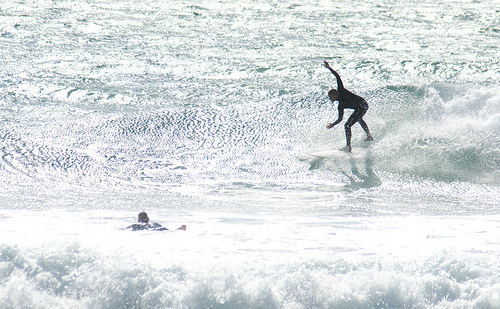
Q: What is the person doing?
A: Surfing.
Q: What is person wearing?
A: Wetsuit.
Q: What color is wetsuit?
A: Black.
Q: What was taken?
A: Picture.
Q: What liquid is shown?
A: Water.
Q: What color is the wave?
A: White.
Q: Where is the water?
A: Behind surfers.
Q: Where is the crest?
A: On wave.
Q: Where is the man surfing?
A: Ocean.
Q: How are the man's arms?
A: Raised.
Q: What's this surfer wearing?
A: Wet suit.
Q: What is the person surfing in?
A: The ocean.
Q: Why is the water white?
A: It's foamy.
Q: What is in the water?
A: Waves.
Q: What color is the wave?
A: White.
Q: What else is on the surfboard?
A: Water.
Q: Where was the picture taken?
A: Outdoors in the water.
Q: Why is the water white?
A: The waves are white.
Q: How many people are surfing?
A: 2 people.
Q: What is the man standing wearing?
A: A wetsuit.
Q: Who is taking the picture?
A: A friend.